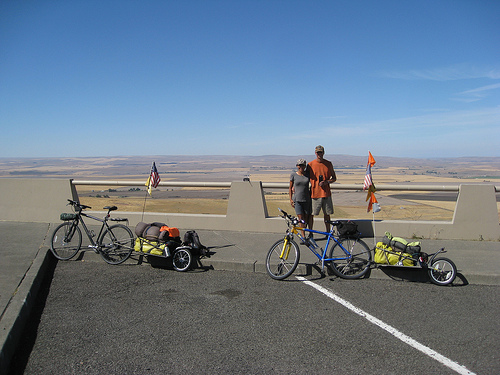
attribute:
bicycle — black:
[54, 196, 136, 270]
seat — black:
[99, 205, 123, 213]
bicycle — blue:
[264, 206, 372, 281]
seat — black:
[322, 218, 347, 227]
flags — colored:
[359, 147, 382, 231]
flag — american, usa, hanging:
[139, 161, 163, 219]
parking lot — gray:
[0, 259, 500, 372]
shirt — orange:
[304, 159, 339, 199]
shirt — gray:
[286, 168, 316, 204]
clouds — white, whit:
[357, 109, 498, 156]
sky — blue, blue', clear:
[3, 1, 499, 158]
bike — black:
[50, 191, 206, 276]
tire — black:
[52, 221, 85, 264]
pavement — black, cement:
[56, 258, 356, 374]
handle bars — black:
[66, 196, 91, 214]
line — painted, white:
[291, 274, 461, 374]